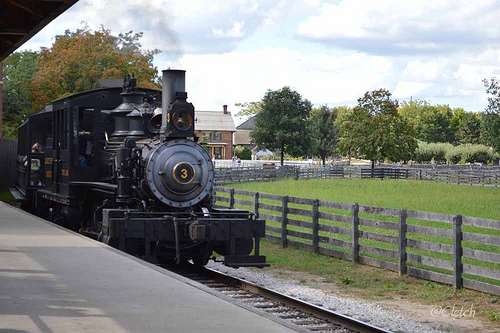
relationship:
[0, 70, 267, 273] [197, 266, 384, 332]
train on track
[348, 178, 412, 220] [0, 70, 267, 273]
grass near train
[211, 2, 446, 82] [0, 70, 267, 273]
sky above train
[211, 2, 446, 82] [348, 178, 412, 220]
sky above grass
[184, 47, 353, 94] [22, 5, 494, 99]
clouds in sky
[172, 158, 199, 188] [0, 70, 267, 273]
3 on train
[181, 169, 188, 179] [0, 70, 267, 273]
3 on train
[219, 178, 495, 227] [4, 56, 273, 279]
field next train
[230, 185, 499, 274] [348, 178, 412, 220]
fence around grass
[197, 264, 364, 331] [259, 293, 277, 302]
track has part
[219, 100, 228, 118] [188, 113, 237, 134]
chimney on roof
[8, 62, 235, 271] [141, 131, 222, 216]
train has front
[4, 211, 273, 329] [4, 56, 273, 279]
sidewalk by train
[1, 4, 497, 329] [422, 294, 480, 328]
picture has wording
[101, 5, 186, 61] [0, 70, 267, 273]
smoke exit train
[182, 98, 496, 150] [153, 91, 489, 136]
tree on background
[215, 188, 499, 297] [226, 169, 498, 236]
fence around field